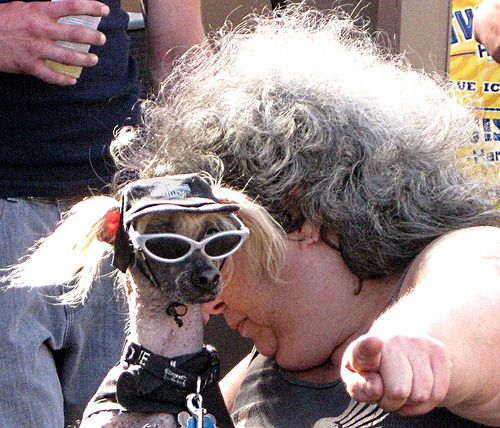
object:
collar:
[106, 346, 237, 408]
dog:
[41, 116, 292, 427]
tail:
[34, 187, 118, 262]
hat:
[81, 130, 285, 246]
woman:
[171, 15, 456, 414]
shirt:
[231, 339, 383, 427]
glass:
[139, 193, 273, 271]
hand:
[292, 280, 456, 419]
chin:
[240, 294, 347, 394]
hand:
[29, 5, 115, 105]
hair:
[274, 66, 333, 139]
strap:
[138, 284, 213, 361]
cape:
[78, 359, 130, 425]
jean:
[0, 227, 148, 422]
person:
[3, 1, 161, 396]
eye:
[217, 218, 262, 262]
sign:
[449, 10, 484, 77]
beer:
[49, 12, 91, 91]